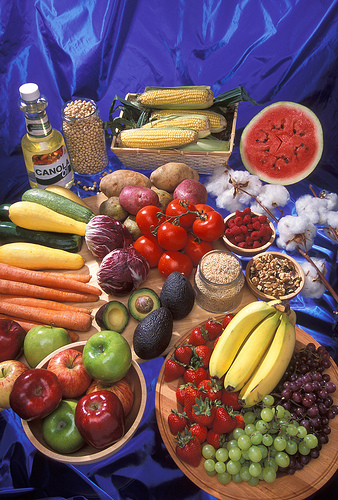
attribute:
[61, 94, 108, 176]
large jar — filled with dried beans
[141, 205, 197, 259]
tomatos — red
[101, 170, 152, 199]
potatoes — brown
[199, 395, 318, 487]
grapes — green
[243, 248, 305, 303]
bowl — wooden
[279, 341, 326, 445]
grapes — purple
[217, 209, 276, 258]
bowl — wooden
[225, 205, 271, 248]
raspberries — red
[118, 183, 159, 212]
potato — purple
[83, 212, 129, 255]
cabbage — purple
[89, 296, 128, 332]
avocado — half 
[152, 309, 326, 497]
tray — round, wooden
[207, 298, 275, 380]
banana — yellow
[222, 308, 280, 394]
banana — yellow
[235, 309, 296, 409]
banana — yellow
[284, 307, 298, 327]
banana — yellow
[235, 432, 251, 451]
grape — green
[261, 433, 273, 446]
grape — green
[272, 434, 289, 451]
grape — green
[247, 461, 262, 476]
grape — green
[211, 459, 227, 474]
grape — green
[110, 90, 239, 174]
basket — whisker, brown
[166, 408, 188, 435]
strawberry — red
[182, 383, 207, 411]
strawberry — red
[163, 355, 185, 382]
strawberry — red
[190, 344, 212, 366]
strawberry — red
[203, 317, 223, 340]
strawberry — red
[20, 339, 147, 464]
bowl — wooden, brown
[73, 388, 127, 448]
apple — deep red, delicious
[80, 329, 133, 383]
apple — green, Granny Smith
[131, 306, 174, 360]
avocado — ripe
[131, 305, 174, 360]
skin — dark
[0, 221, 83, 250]
squash — green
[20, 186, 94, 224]
squash — green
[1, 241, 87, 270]
squash — yellow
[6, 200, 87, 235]
squash — yellow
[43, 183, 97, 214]
squash — yellow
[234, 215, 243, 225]
raspberry — red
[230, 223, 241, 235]
raspberry — red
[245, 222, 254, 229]
raspberry — red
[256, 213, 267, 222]
raspberry — red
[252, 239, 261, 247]
raspberry — red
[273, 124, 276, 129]
seed — black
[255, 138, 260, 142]
seed — black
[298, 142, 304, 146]
seed — black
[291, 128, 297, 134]
seed — black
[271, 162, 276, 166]
seed — black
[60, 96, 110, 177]
jar — clear, glass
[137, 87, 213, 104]
corn — yellow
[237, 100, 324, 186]
watermelon — cut, open, ripe, cut in half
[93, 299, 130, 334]
avocado — cut, halved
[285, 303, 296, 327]
banana — yellow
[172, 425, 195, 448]
stem — green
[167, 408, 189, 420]
stem — green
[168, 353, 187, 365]
stem — green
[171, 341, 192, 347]
stem — green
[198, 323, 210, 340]
stem — green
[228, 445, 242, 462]
grape — green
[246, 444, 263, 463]
grape — green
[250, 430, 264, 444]
grape — green